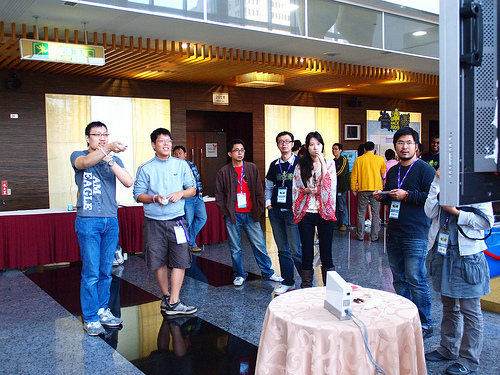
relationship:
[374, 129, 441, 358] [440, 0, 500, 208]
person looking at tv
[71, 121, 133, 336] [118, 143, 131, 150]
man pointing remote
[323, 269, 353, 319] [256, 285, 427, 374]
wii on table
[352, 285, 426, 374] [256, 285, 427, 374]
tablecloth on table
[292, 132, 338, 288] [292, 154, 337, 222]
woman with sweater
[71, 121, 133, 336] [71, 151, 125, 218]
man has shirt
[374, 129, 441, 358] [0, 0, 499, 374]
person in photo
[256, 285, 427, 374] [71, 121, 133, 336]
table in front of man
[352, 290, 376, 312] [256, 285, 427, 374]
sheet on table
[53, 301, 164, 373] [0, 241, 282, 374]
reflection on floor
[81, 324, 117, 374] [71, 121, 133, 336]
reflection of a man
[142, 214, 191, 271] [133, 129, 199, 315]
shorts on person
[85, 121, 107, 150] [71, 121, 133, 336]
head of a man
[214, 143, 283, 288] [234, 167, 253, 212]
man in a shirt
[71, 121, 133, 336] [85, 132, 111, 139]
man wearing glasses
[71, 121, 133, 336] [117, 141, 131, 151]
man playing game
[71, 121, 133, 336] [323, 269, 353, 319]
man playing wii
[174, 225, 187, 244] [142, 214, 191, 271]
tag on shorts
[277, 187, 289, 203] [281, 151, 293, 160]
tag around neck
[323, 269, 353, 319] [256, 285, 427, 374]
wii sitting on table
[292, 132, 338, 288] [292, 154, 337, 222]
woman has sweater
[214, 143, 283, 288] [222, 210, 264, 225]
man with hands in pocket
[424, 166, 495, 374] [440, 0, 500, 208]
woman standing behind tv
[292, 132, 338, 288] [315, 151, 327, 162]
woman has hand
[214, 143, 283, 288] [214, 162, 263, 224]
man wearing jacket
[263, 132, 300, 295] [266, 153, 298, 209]
man wearing sweater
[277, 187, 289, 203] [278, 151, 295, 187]
tag on lanyard